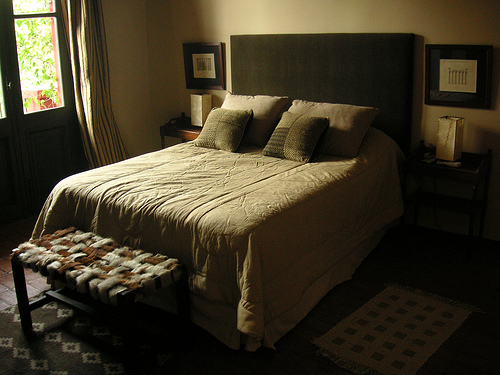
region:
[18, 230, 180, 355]
brown and white bench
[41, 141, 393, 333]
tan comforter on bed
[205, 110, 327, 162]
green and tan pillows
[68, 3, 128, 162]
tan drapes on window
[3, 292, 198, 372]
tan and white rug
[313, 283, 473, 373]
white and grey rug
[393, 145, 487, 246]
brown wood side table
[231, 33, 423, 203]
green fabric head board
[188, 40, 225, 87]
picture hanging on wall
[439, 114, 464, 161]
bag lamp on table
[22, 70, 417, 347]
made bed with four pillows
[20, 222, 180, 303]
seat of bench at foot of bed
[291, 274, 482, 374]
rug beside bed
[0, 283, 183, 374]
rug in front of bed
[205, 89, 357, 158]
four pillows propped on bed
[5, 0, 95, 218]
double doors leading to outside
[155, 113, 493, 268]
nightstands beside the bed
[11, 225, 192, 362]
bench at the foot of bed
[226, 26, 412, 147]
headboard of the bed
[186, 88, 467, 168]
lamps sitting on nightstands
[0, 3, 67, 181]
Clear grass on a dark framed door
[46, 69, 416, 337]
Bed with beddings spread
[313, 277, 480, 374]
Checked mat on the floor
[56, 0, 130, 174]
Long curtain with longs stripes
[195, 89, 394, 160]
Pillows at the head of the bed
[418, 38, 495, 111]
Framed image on the wall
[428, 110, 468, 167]
Box shaped, light brown lamp shade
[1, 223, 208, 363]
Low table with covering at the base of the bed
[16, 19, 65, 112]
Green plant leaves visible through the door glass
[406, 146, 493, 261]
Dark brown bedside table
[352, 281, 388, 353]
part of a carpet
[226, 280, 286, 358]
part of a sheet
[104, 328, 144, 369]
part of a stand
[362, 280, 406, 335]
part of a floor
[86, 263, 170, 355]
part of a stool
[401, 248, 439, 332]
part of a carpet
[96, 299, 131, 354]
part of a stand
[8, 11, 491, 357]
neat and symmetrical bedroom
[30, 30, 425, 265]
green headboard, bedspread and pillows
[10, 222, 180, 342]
bench at foot of bed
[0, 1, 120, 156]
striped curtain by window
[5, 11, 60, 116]
glass pane showing leaves and red railing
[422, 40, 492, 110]
lines in a square frame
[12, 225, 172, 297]
thick woven strips in brown and white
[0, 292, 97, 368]
rug with white diamond pattern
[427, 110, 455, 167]
short and rectangular lampshade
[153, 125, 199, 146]
top of wooden night table